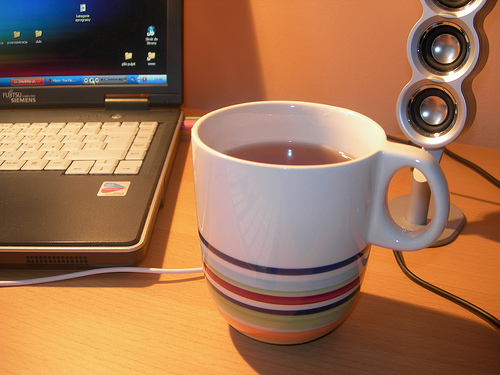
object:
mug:
[192, 99, 447, 346]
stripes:
[198, 230, 373, 278]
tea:
[224, 140, 355, 167]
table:
[0, 105, 500, 374]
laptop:
[0, 0, 184, 269]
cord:
[0, 266, 204, 288]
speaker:
[397, 0, 487, 149]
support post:
[387, 149, 467, 248]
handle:
[370, 140, 452, 253]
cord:
[390, 250, 500, 331]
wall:
[184, 0, 499, 145]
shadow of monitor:
[184, 0, 268, 113]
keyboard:
[0, 119, 180, 180]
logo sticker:
[96, 180, 131, 197]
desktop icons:
[77, 1, 92, 13]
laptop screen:
[0, 0, 169, 88]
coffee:
[224, 141, 358, 165]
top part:
[423, 0, 489, 15]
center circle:
[405, 16, 480, 83]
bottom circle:
[396, 74, 468, 150]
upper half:
[192, 141, 373, 266]